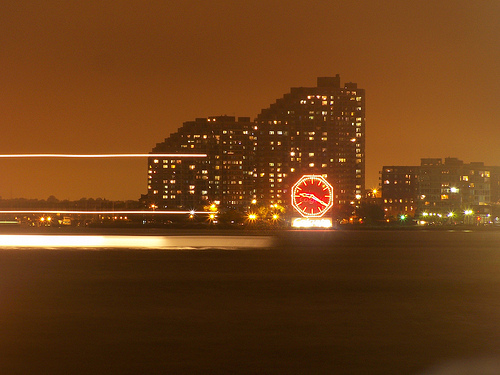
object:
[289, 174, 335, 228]
lights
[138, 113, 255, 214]
buildings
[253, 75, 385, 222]
building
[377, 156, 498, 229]
building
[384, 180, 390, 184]
light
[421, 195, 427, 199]
light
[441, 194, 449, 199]
light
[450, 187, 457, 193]
glaring light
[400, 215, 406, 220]
glaring light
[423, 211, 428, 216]
glaring light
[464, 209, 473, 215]
glaring light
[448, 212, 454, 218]
glaring light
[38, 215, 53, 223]
lights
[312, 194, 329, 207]
long hand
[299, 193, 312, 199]
short hand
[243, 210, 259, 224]
light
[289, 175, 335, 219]
clock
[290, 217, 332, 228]
light